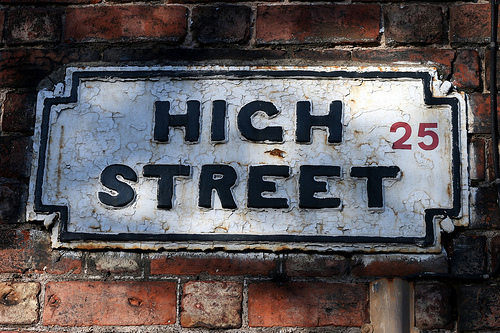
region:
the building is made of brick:
[147, 9, 478, 53]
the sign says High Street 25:
[69, 58, 496, 261]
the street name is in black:
[85, 74, 402, 240]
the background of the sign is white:
[84, 95, 438, 260]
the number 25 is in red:
[385, 107, 447, 170]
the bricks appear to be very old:
[52, 270, 243, 324]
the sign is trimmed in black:
[23, 43, 483, 260]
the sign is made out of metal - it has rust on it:
[66, 241, 451, 282]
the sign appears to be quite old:
[73, 54, 460, 260]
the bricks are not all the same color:
[79, 7, 454, 37]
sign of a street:
[16, 47, 484, 277]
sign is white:
[14, 43, 486, 273]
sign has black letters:
[20, 43, 486, 277]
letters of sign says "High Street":
[81, 86, 407, 232]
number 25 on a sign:
[371, 102, 451, 167]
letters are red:
[377, 107, 452, 164]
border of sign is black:
[21, 45, 481, 268]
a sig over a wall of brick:
[3, 12, 498, 327]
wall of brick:
[8, 250, 493, 332]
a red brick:
[61, 6, 189, 45]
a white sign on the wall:
[23, 62, 474, 258]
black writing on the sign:
[94, 95, 403, 216]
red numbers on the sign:
[386, 117, 441, 156]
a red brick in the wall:
[38, 270, 181, 327]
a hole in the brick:
[123, 287, 148, 312]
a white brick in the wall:
[177, 275, 246, 332]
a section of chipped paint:
[261, 143, 288, 159]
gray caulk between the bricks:
[174, 4, 201, 48]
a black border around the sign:
[32, 69, 462, 247]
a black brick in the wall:
[188, 2, 257, 45]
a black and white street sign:
[26, 47, 497, 282]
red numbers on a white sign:
[378, 108, 451, 156]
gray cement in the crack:
[173, 282, 183, 317]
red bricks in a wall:
[46, 270, 365, 331]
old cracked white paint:
[81, 119, 138, 155]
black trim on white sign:
[149, 225, 428, 249]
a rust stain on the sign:
[268, 145, 293, 157]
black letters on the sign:
[97, 160, 416, 220]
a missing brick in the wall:
[367, 287, 420, 332]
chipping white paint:
[89, 121, 141, 151]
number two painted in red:
[388, 121, 413, 151]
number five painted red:
[416, 121, 439, 153]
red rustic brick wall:
[0, 0, 499, 331]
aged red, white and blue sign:
[22, 55, 470, 254]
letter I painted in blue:
[209, 97, 231, 148]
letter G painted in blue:
[237, 95, 288, 146]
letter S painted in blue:
[93, 162, 140, 210]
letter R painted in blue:
[196, 161, 240, 211]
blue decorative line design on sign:
[30, 65, 461, 243]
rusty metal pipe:
[355, 276, 417, 331]